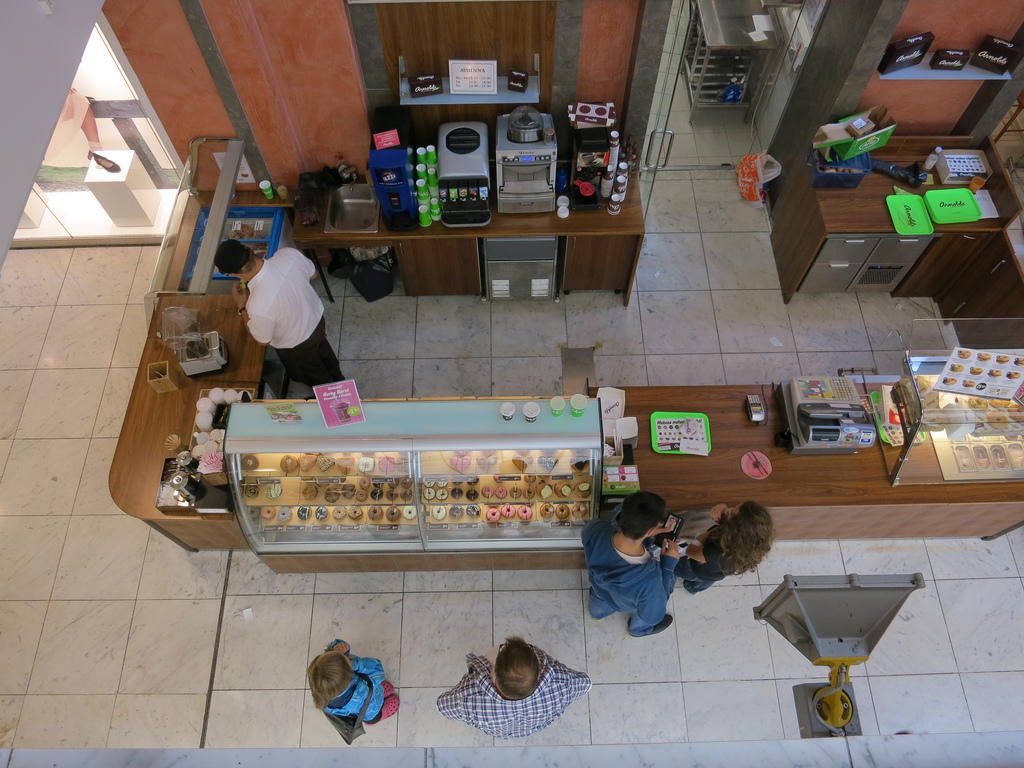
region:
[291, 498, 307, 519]
donut in the display case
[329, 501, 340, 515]
donut in the display case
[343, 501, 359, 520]
donut in the display case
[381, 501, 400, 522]
donut in the display case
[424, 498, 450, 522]
donut in the display case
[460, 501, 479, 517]
donut in the display case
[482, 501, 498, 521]
donut in the display case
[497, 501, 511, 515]
donut in the display case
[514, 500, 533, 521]
donut in the display case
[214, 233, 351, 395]
the employee standing by the counter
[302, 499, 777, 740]
customers standing in line at the store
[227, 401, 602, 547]
a display case filled with many donuts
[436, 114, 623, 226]
assorted drink mashines sitting on the counter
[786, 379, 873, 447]
the cash registers sitting on the counter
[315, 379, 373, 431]
a pink sign sitting on the counter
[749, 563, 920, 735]
a television attached to a pole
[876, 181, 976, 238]
some trays sitting on the counter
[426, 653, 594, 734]
the striped shirt the man is wearing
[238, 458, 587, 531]
Doughnuts inside of a display case.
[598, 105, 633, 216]
Cups stacked up.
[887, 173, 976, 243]
Lime green trays.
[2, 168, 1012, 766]
Off-white colored tiles on the ground.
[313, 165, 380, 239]
A silver sink area.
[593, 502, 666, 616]
a person standing at the counter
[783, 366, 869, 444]
a cash register on the counter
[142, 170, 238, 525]
a wooden counter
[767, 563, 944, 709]
a light hanging from the wall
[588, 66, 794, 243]
two glass doors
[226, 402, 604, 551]
a glass display case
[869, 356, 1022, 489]
a glass display case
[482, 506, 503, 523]
a pink frosted doughnut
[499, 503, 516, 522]
a pink frosted doughnut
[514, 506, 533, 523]
a pink frosted doughnut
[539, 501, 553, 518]
a brown frosted doughnut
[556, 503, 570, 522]
a brown frosted doughnut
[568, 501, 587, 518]
a brown frosted doughnut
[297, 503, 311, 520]
a chocolate frosted doughnut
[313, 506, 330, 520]
a chocolate frosted doughnut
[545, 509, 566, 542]
a donut on display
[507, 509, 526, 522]
a donut on display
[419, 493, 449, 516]
a donut on display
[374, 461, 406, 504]
a donut on display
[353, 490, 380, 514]
a donut on display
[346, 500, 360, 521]
a donut on display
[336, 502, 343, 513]
a donut on display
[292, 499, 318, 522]
a donut on display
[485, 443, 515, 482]
a donut on display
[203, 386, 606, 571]
a display case of baked food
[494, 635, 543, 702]
a man's short cut brown hair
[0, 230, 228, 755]
white tile floor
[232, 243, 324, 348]
a man's short sleeve white shirt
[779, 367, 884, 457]
a cash register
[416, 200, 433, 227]
a stack of green and white cups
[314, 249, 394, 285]
a black trash bag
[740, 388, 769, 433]
a small credit card machine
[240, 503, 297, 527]
a bunch of donuts in a glass display case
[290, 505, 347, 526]
a bunch of donuts in a glass display case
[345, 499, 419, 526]
a bunch of donuts in a glass display case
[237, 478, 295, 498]
a bunch of donuts in a glass display case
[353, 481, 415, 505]
a bunch of donuts in a glass display case